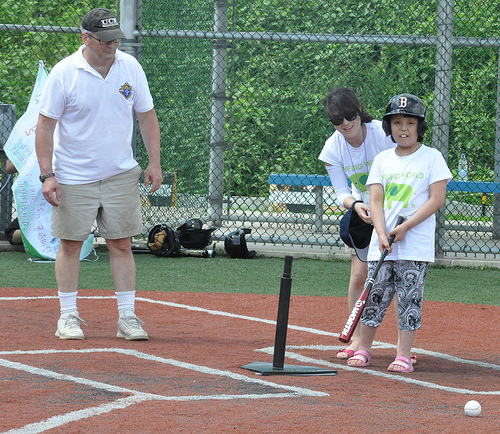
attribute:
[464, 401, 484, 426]
baseball — round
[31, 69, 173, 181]
shirt — white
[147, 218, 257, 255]
equipment — Distant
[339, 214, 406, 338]
bat — black, red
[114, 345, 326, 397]
line — white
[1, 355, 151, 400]
line — white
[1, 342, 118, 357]
line — white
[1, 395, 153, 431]
line — white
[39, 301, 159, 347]
shoes — white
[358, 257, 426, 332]
black pants — white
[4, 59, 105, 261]
bags — black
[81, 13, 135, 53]
cap — black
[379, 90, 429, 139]
helmet — black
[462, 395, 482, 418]
ball — white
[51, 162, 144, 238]
shorts — tan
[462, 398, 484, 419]
baseball — white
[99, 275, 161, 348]
sock — white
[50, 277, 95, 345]
sock — white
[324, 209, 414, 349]
bat — baseball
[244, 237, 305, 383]
stick — black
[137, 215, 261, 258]
bags — black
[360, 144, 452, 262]
shirt — white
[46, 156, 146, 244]
shorts — khaki